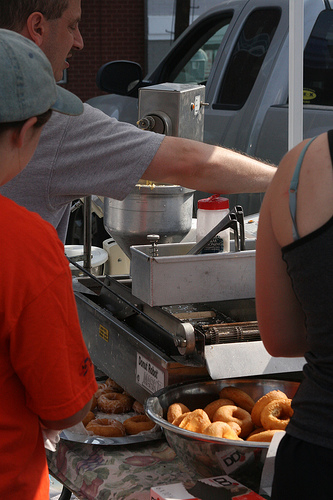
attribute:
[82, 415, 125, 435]
donut — cooked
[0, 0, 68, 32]
hair — short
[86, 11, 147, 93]
building — red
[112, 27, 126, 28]
cement — grey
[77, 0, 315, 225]
truck — silver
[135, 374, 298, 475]
donuts — brown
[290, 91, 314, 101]
sticker — yellow, oval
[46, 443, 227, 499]
tablecloth — colorful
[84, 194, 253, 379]
doughnut fryer — large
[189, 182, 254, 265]
bottle — red, white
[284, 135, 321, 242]
strap — light blue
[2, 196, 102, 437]
shirt — red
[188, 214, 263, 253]
tongs — silver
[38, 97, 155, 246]
shirt — grey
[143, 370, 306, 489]
bowl — large, gray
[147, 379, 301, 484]
bowl — metal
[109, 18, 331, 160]
silver truck — shiny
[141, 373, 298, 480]
donut bowl — metal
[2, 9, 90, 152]
cap — blue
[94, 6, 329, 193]
truck — white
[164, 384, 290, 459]
donuts — brown 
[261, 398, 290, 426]
doughnut — large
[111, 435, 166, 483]
patter — floral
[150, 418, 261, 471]
bowl — metal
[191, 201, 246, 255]
spatulas — metal